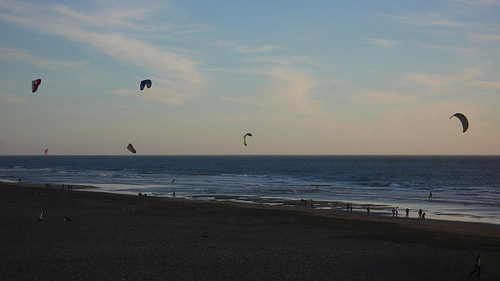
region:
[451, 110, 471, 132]
kite in the air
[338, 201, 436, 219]
people walking on beach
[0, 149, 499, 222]
dark blue ocean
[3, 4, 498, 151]
blue sky with clouds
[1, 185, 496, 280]
brown sandy beach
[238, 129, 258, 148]
silver kite in the sky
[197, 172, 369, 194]
light blue ocean ripples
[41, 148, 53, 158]
kite far in the distance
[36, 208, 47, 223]
person alone on the beach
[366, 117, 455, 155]
light pink area in the sky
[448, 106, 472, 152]
Large kite flying in sky.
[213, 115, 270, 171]
Large kite flying in sky.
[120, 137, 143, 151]
Large kite flying in sky.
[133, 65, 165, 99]
Large kite is flying in sky.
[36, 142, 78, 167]
Large kite is flying in sky.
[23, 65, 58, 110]
Large kite is flying in sky.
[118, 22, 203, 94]
White clouds in sky.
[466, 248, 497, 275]
Person walking on beach.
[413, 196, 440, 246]
People standing near water.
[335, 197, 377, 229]
People standing near water.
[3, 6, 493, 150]
Clouds are in the sky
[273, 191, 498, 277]
People are on the beach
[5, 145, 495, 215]
An ocean is in the background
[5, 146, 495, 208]
Ocean water is blue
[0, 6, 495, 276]
Photo was taken outdoors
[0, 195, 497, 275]
Sand is dark brown in color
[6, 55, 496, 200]
paraglidingers are in the sky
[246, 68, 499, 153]
Clouds have a light pink color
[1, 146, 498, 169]
Horizon where the ocean meets the sky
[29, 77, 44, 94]
triangle shaped kite in sky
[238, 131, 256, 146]
silver curved kite in sky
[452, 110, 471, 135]
boomerang shaped kite in sky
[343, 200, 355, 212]
two people standing together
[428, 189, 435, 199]
person alone in the water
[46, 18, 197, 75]
cloud in the sky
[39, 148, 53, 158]
kite on the horizon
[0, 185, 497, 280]
dark brown sandy beach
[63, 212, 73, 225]
small object on the beach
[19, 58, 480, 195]
Six kites in the sky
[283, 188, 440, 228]
man people standing on the beach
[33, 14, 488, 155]
white wispy clouds in the sky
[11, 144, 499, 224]
blue water coming to shore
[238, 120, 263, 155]
a green kite in the sky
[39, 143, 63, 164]
a red kite in the distance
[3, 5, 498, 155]
a blue sky with white clouds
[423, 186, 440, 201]
one person out in the water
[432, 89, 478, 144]
One kite curved like a backwards c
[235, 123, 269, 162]
One kite looks like a foward c